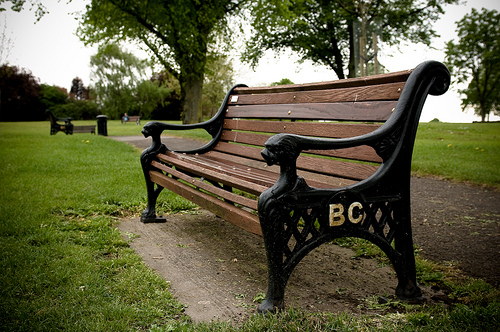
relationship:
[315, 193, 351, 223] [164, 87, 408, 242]
letters on bench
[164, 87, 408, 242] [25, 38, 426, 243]
bench in park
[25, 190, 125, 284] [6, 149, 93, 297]
grass in field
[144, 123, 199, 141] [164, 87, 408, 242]
iron on bench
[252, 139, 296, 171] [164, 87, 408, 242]
animal on bench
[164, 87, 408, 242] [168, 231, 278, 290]
bench on cement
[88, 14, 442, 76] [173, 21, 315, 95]
trees in middle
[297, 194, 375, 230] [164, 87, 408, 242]
bc on bench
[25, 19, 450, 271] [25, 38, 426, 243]
scene of park